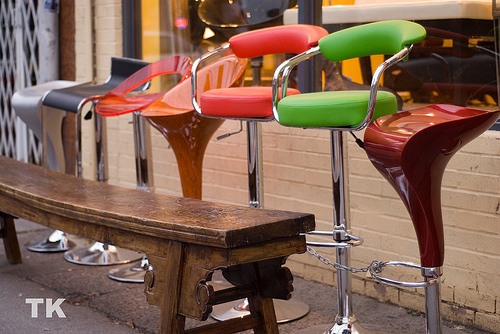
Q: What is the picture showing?
A: It is showing a sidewalk.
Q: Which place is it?
A: It is a sidewalk.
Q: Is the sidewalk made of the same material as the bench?
A: No, the sidewalk is made of cement and the bench is made of wood.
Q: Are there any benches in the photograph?
A: Yes, there is a bench.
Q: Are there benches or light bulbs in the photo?
A: Yes, there is a bench.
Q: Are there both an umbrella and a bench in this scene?
A: No, there is a bench but no umbrellas.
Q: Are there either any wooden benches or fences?
A: Yes, there is a wood bench.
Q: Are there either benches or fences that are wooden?
A: Yes, the bench is wooden.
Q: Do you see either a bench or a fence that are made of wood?
A: Yes, the bench is made of wood.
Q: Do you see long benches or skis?
A: Yes, there is a long bench.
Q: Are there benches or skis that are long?
A: Yes, the bench is long.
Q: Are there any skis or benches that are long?
A: Yes, the bench is long.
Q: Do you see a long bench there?
A: Yes, there is a long bench.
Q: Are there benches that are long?
A: Yes, there is a bench that is long.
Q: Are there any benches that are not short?
A: Yes, there is a long bench.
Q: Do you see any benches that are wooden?
A: Yes, there is a wood bench.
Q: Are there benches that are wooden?
A: Yes, there is a bench that is wooden.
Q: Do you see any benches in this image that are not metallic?
A: Yes, there is a wooden bench.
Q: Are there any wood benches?
A: Yes, there is a bench that is made of wood.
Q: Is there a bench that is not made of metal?
A: Yes, there is a bench that is made of wood.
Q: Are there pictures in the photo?
A: No, there are no pictures.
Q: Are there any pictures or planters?
A: No, there are no pictures or planters.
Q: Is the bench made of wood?
A: Yes, the bench is made of wood.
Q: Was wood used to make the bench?
A: Yes, the bench is made of wood.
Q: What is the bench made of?
A: The bench is made of wood.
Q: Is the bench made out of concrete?
A: No, the bench is made of wood.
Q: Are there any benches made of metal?
A: No, there is a bench but it is made of wood.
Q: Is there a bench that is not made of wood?
A: No, there is a bench but it is made of wood.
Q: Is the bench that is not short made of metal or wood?
A: The bench is made of wood.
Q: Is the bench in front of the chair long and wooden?
A: Yes, the bench is long and wooden.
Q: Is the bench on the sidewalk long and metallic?
A: No, the bench is long but wooden.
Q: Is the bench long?
A: Yes, the bench is long.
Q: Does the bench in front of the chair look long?
A: Yes, the bench is long.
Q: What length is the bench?
A: The bench is long.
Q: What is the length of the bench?
A: The bench is long.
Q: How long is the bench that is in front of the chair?
A: The bench is long.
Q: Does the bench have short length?
A: No, the bench is long.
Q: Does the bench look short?
A: No, the bench is long.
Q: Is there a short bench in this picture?
A: No, there is a bench but it is long.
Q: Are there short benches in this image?
A: No, there is a bench but it is long.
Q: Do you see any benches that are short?
A: No, there is a bench but it is long.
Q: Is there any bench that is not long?
A: No, there is a bench but it is long.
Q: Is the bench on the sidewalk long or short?
A: The bench is long.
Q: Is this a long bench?
A: Yes, this is a long bench.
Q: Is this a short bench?
A: No, this is a long bench.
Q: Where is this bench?
A: The bench is on the sidewalk.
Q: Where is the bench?
A: The bench is on the sidewalk.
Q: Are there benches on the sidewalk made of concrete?
A: Yes, there is a bench on the sidewalk.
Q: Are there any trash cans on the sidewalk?
A: No, there is a bench on the sidewalk.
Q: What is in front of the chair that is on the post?
A: The bench is in front of the chair.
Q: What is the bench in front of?
A: The bench is in front of the chair.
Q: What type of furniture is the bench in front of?
A: The bench is in front of the chair.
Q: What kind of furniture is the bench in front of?
A: The bench is in front of the chair.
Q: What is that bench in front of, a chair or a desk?
A: The bench is in front of a chair.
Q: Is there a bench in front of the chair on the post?
A: Yes, there is a bench in front of the chair.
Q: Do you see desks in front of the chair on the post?
A: No, there is a bench in front of the chair.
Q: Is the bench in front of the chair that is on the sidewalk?
A: Yes, the bench is in front of the chair.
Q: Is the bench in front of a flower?
A: No, the bench is in front of the chair.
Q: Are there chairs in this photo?
A: Yes, there is a chair.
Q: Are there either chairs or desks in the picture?
A: Yes, there is a chair.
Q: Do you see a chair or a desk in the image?
A: Yes, there is a chair.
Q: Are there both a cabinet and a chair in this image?
A: No, there is a chair but no cabinets.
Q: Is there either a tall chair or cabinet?
A: Yes, there is a tall chair.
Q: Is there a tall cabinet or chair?
A: Yes, there is a tall chair.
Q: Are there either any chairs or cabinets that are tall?
A: Yes, the chair is tall.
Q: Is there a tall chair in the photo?
A: Yes, there is a tall chair.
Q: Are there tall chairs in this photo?
A: Yes, there is a tall chair.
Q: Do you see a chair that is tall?
A: Yes, there is a chair that is tall.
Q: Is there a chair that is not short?
A: Yes, there is a tall chair.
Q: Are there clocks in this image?
A: No, there are no clocks.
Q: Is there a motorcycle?
A: No, there are no motorcycles.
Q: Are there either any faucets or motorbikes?
A: No, there are no motorbikes or faucets.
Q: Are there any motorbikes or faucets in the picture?
A: No, there are no motorbikes or faucets.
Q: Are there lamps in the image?
A: No, there are no lamps.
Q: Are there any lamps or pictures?
A: No, there are no lamps or pictures.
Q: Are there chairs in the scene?
A: Yes, there is a chair.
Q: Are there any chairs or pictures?
A: Yes, there is a chair.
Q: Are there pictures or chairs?
A: Yes, there is a chair.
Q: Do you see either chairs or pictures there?
A: Yes, there is a chair.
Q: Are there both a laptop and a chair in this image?
A: No, there is a chair but no laptops.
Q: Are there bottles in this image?
A: No, there are no bottles.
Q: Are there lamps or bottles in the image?
A: No, there are no bottles or lamps.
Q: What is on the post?
A: The chair is on the post.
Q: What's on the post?
A: The chair is on the post.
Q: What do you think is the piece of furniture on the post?
A: The piece of furniture is a chair.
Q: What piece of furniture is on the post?
A: The piece of furniture is a chair.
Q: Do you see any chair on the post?
A: Yes, there is a chair on the post.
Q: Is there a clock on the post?
A: No, there is a chair on the post.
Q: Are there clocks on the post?
A: No, there is a chair on the post.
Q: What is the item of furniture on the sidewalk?
A: The piece of furniture is a chair.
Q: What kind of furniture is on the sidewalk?
A: The piece of furniture is a chair.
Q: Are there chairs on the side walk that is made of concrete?
A: Yes, there is a chair on the sidewalk.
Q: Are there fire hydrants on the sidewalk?
A: No, there is a chair on the sidewalk.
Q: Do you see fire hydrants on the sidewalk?
A: No, there is a chair on the sidewalk.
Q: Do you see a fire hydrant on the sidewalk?
A: No, there is a chair on the sidewalk.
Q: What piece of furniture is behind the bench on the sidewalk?
A: The piece of furniture is a chair.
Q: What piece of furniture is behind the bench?
A: The piece of furniture is a chair.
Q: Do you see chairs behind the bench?
A: Yes, there is a chair behind the bench.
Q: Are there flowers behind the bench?
A: No, there is a chair behind the bench.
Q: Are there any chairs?
A: Yes, there is a chair.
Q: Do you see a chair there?
A: Yes, there is a chair.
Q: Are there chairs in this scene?
A: Yes, there is a chair.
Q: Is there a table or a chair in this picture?
A: Yes, there is a chair.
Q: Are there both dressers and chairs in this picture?
A: No, there is a chair but no dressers.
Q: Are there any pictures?
A: No, there are no pictures.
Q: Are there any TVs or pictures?
A: No, there are no pictures or tvs.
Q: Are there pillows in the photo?
A: No, there are no pillows.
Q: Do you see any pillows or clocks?
A: No, there are no pillows or clocks.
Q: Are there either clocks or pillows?
A: No, there are no pillows or clocks.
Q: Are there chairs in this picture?
A: Yes, there is a chair.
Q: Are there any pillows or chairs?
A: Yes, there is a chair.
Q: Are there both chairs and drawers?
A: No, there is a chair but no drawers.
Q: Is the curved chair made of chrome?
A: Yes, the chair is made of chrome.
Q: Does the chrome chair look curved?
A: Yes, the chair is curved.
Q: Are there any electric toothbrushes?
A: No, there are no electric toothbrushes.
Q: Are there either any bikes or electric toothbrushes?
A: No, there are no electric toothbrushes or bikes.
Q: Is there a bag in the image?
A: No, there are no bags.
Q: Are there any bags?
A: No, there are no bags.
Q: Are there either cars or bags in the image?
A: No, there are no bags or cars.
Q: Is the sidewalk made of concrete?
A: Yes, the sidewalk is made of concrete.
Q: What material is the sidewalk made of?
A: The sidewalk is made of concrete.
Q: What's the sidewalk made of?
A: The sidewalk is made of concrete.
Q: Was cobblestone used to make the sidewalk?
A: No, the sidewalk is made of concrete.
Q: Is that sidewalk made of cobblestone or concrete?
A: The sidewalk is made of concrete.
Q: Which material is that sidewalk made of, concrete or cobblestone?
A: The sidewalk is made of concrete.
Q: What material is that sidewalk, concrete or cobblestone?
A: The sidewalk is made of concrete.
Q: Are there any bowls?
A: No, there are no bowls.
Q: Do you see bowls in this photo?
A: No, there are no bowls.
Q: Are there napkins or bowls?
A: No, there are no bowls or napkins.